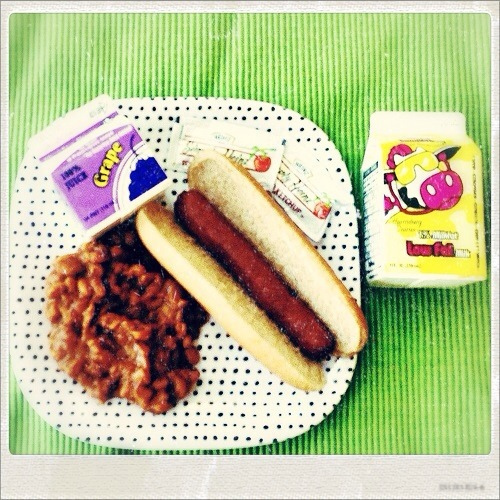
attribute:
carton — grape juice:
[36, 99, 171, 225]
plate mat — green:
[364, 349, 494, 459]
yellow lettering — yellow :
[86, 139, 127, 187]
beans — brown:
[37, 234, 222, 427]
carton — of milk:
[355, 106, 489, 294]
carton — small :
[344, 106, 489, 307]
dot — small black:
[299, 127, 304, 132]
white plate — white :
[358, 68, 484, 318]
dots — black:
[209, 366, 264, 431]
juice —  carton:
[24, 92, 171, 236]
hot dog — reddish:
[169, 187, 329, 348]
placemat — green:
[7, 13, 492, 456]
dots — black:
[31, 99, 361, 450]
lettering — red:
[407, 239, 455, 258]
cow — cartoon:
[377, 140, 462, 217]